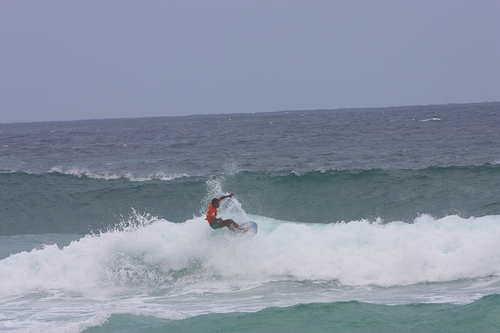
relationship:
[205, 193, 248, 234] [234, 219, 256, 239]
man on board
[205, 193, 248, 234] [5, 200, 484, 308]
man surfing a wave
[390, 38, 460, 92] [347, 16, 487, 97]
clouds are floating in sky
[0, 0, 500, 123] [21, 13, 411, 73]
clouds are floating in sky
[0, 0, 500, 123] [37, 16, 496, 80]
clouds are floating in sky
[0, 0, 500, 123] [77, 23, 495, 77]
clouds are floating in sky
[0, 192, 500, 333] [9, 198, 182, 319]
wave on top of water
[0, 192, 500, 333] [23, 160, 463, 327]
wave on top of water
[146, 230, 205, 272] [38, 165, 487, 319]
wave on top of water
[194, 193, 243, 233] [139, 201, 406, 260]
man on top of wave